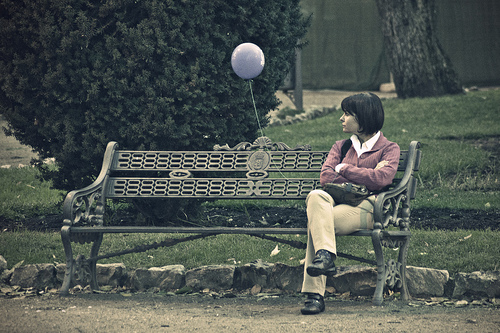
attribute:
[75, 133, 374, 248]
bench — gray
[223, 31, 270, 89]
balloon — purple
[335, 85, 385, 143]
hair — black, short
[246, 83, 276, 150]
string — thin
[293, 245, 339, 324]
shoes — black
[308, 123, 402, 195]
blazer — brown, red